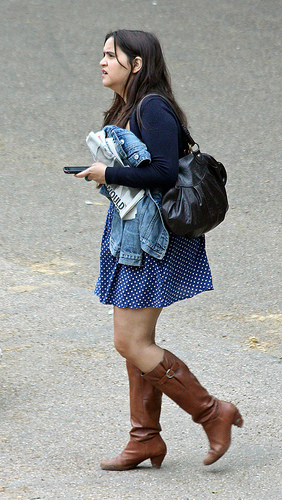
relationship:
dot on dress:
[99, 253, 105, 259] [88, 98, 220, 311]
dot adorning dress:
[147, 259, 150, 261] [92, 191, 214, 309]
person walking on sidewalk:
[62, 28, 244, 476] [10, 320, 276, 497]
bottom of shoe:
[105, 460, 161, 467] [100, 359, 166, 472]